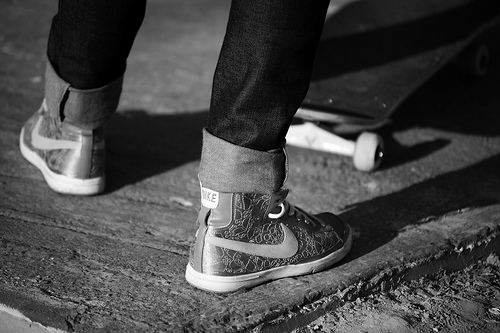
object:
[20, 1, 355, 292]
person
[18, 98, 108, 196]
shoe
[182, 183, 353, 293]
shoe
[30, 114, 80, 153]
logo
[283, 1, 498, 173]
skateboard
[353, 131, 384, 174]
wheel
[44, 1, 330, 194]
pants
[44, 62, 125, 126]
cuff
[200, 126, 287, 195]
cuff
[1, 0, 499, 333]
ground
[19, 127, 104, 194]
sole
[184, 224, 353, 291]
sole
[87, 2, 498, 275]
shadow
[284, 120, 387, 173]
axle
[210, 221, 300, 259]
logo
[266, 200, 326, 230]
laces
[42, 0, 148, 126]
leg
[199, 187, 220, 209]
logo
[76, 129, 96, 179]
stripe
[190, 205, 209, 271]
stripe